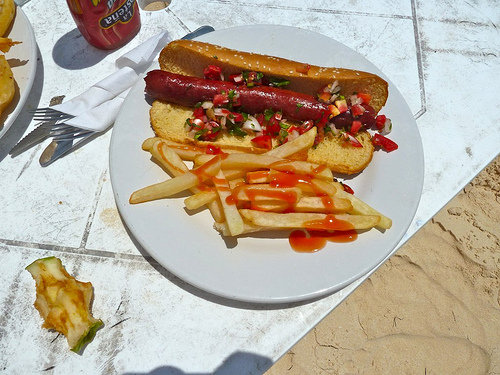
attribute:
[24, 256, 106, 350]
apple — half eaten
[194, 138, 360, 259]
ketchup — red tomato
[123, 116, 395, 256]
fries — french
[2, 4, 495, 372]
top — white, tile, table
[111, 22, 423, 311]
plate — white, dinner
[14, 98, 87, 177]
knives — butter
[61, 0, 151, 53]
half — bottom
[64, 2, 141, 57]
bottle — red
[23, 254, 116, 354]
core — green apple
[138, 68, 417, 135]
hotdog — red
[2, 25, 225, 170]
utensils — wrapped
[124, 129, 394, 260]
fries — lightly browned, french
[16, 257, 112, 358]
apple — eaten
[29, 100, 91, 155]
fork — wrapped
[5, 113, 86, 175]
knife — wrapped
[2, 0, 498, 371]
table — dirty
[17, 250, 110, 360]
apple — green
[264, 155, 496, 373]
sand — tan-colored, brown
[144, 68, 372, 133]
hot dog — red, tan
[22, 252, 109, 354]
apple core — browning, pictured